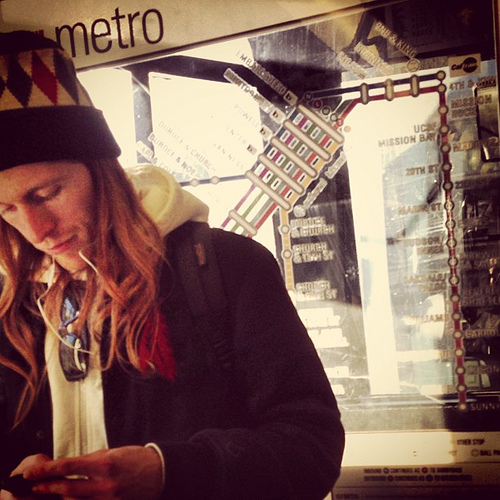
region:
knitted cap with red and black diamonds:
[5, 24, 120, 171]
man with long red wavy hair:
[3, 152, 177, 437]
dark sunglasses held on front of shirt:
[40, 272, 98, 383]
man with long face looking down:
[3, 149, 102, 277]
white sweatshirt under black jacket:
[5, 157, 348, 494]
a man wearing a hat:
[1, 30, 179, 305]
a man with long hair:
[7, 47, 210, 411]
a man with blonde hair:
[1, 55, 149, 319]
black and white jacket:
[40, 197, 375, 492]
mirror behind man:
[114, 49, 481, 494]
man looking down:
[12, 99, 248, 490]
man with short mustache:
[14, 108, 200, 398]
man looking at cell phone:
[0, 29, 347, 497]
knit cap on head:
[0, 28, 120, 171]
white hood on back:
[123, 159, 210, 230]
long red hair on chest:
[1, 159, 158, 427]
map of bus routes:
[110, 8, 494, 497]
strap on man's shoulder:
[171, 220, 243, 382]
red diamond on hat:
[25, 46, 61, 104]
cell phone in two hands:
[0, 438, 154, 498]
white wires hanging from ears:
[33, 223, 118, 359]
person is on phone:
[0, 27, 344, 498]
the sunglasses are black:
[57, 277, 95, 383]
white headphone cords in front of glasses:
[37, 215, 115, 357]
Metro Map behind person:
[74, 0, 499, 498]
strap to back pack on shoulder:
[175, 217, 237, 377]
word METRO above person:
[54, 5, 167, 65]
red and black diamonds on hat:
[0, 50, 97, 110]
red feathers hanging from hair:
[133, 298, 180, 386]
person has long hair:
[0, 153, 178, 428]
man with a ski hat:
[0, 27, 128, 169]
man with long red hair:
[79, 148, 168, 381]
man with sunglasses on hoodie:
[60, 275, 92, 379]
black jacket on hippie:
[5, 226, 347, 498]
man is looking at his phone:
[2, 23, 347, 498]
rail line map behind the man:
[203, 45, 498, 417]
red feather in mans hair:
[129, 286, 194, 388]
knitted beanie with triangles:
[12, 42, 116, 154]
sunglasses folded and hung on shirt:
[36, 263, 100, 398]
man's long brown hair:
[70, 151, 185, 377]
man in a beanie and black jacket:
[30, 30, 308, 485]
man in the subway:
[6, 30, 342, 496]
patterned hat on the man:
[1, 30, 113, 172]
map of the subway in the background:
[70, 0, 495, 427]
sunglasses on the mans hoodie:
[45, 267, 85, 382]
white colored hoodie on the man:
[35, 157, 220, 497]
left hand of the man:
[35, 435, 160, 485]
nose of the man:
[13, 198, 54, 244]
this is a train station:
[9, 15, 496, 474]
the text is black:
[52, 3, 188, 78]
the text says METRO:
[57, 4, 177, 71]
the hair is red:
[64, 182, 156, 354]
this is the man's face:
[19, 183, 98, 273]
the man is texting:
[21, 393, 96, 493]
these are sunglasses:
[8, 295, 85, 393]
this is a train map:
[214, 53, 446, 378]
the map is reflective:
[269, 127, 436, 359]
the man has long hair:
[0, 152, 170, 399]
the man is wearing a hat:
[1, 28, 121, 165]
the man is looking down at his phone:
[1, 35, 293, 498]